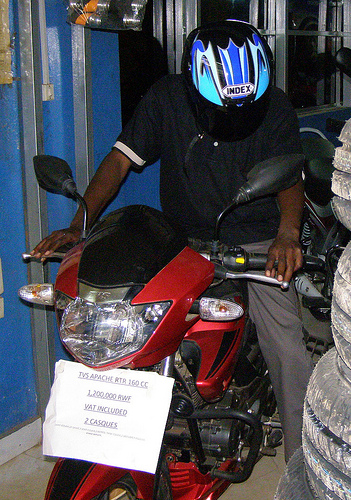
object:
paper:
[42, 359, 175, 474]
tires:
[329, 116, 351, 231]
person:
[31, 18, 312, 462]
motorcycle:
[17, 155, 324, 500]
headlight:
[57, 299, 171, 370]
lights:
[199, 297, 244, 322]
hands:
[265, 236, 303, 291]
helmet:
[180, 18, 275, 142]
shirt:
[111, 74, 303, 245]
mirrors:
[229, 154, 306, 203]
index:
[226, 85, 252, 96]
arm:
[29, 78, 163, 261]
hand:
[31, 226, 76, 264]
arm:
[264, 99, 305, 288]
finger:
[265, 248, 275, 277]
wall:
[0, 0, 117, 464]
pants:
[247, 238, 315, 466]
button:
[235, 257, 244, 265]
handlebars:
[22, 245, 326, 289]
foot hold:
[258, 441, 275, 458]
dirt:
[273, 117, 349, 499]